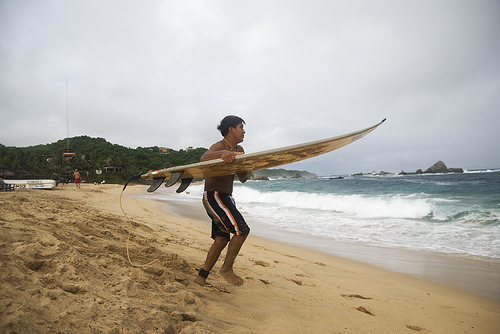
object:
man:
[192, 115, 250, 289]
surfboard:
[141, 117, 387, 194]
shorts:
[201, 190, 251, 241]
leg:
[201, 194, 250, 271]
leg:
[194, 199, 230, 280]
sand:
[0, 192, 107, 334]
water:
[345, 179, 499, 235]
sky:
[1, 1, 500, 114]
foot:
[218, 265, 247, 287]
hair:
[215, 114, 246, 138]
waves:
[231, 185, 500, 259]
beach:
[0, 180, 499, 333]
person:
[73, 168, 82, 189]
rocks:
[425, 160, 466, 174]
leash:
[119, 172, 157, 269]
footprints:
[349, 302, 379, 318]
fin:
[145, 176, 165, 193]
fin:
[164, 170, 184, 187]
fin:
[175, 176, 196, 193]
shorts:
[75, 178, 81, 185]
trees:
[0, 149, 16, 161]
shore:
[157, 176, 499, 264]